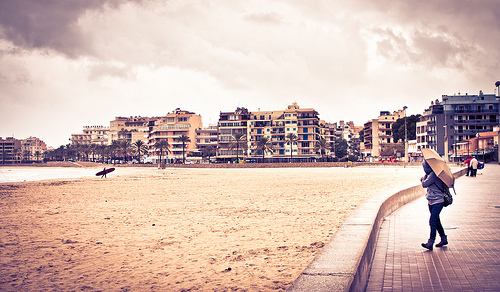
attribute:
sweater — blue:
[422, 176, 452, 206]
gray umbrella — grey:
[422, 145, 457, 192]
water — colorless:
[0, 166, 137, 179]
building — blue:
[445, 92, 498, 167]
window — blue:
[249, 120, 310, 152]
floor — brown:
[168, 182, 288, 282]